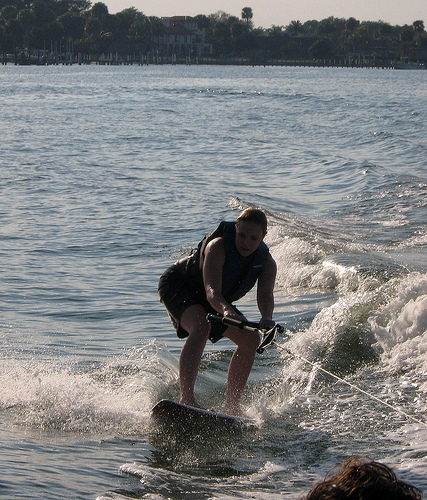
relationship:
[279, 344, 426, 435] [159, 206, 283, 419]
string running from woman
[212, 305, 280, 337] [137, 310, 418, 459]
handle of jet ski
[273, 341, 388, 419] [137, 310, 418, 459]
wire of jet ski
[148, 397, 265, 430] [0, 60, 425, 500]
wakeboard sticking out of water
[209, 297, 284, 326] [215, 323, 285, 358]
hands holding handlebar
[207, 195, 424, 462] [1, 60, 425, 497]
wave in water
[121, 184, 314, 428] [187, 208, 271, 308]
woman has vest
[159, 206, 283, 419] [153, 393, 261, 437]
woman on jet ski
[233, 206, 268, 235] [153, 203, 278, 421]
hair of person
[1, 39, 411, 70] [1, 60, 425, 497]
poles coming out of water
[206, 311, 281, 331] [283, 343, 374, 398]
handle at end of rope